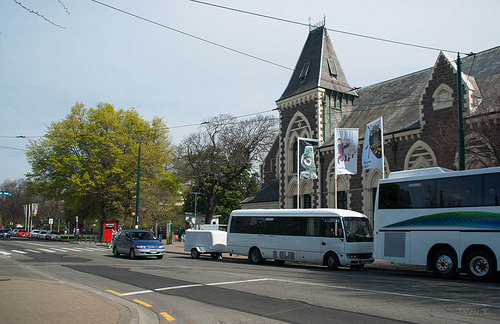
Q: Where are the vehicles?
A: On the street.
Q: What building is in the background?
A: A church.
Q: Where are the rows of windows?
A: On the buses.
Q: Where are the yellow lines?
A: On the roadway.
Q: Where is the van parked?
A: Behind the bus.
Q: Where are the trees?
A: On the roadside.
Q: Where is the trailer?
A: Behind the van.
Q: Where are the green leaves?
A: On the trees.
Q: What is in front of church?
A: Bus, van and trailer.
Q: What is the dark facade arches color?
A: White.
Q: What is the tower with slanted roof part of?
A: Church corner.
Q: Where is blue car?
A: Driving on street.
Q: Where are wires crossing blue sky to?
A: Church.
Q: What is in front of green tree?
A: Tree with bare branches.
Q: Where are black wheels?
A: White vehicles.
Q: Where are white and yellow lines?
A: Street.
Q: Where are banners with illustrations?
A: Front of church.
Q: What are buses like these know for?
A: Traveling long distances.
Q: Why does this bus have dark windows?
A: Windows are tinted for privacy.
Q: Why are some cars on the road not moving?
A: Those vehicles are parked.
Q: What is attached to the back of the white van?
A: Trailer.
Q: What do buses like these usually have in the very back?
A: Bathrooms.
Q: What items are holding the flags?
A: White poles.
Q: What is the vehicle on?
A: Road.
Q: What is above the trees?
A: Wire cable.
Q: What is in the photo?
A: Trees.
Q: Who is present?
A: No one.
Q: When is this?
A: Daytime.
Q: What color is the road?
A: Gray.